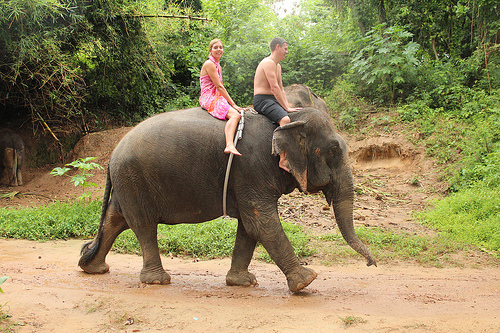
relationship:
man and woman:
[252, 32, 301, 92] [197, 37, 243, 158]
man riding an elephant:
[252, 32, 301, 92] [33, 60, 386, 328]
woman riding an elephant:
[197, 37, 243, 158] [33, 60, 386, 328]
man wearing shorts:
[252, 37, 293, 173] [256, 88, 283, 123]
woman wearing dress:
[197, 37, 243, 158] [194, 57, 234, 131]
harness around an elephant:
[222, 110, 247, 217] [85, 90, 374, 306]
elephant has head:
[77, 84, 378, 293] [266, 93, 377, 271]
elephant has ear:
[77, 84, 378, 293] [265, 115, 311, 196]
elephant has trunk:
[77, 104, 382, 297] [319, 162, 382, 274]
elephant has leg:
[77, 104, 382, 297] [234, 185, 319, 299]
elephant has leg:
[77, 104, 382, 297] [223, 211, 262, 290]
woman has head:
[197, 37, 243, 158] [205, 35, 227, 64]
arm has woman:
[201, 59, 245, 116] [197, 37, 243, 158]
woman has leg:
[197, 37, 243, 158] [201, 94, 244, 162]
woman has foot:
[197, 37, 243, 158] [215, 139, 242, 162]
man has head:
[252, 37, 293, 173] [265, 35, 295, 65]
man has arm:
[252, 37, 293, 173] [259, 59, 299, 116]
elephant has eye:
[77, 84, 378, 293] [328, 141, 342, 155]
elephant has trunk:
[77, 104, 382, 297] [317, 164, 383, 268]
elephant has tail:
[77, 84, 378, 293] [72, 157, 114, 267]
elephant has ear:
[77, 104, 382, 297] [264, 115, 321, 198]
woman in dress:
[190, 31, 243, 161] [195, 51, 233, 127]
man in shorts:
[252, 37, 293, 173] [252, 90, 300, 177]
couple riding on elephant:
[195, 35, 306, 180] [77, 104, 382, 297]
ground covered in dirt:
[3, 235, 496, 332] [0, 235, 499, 331]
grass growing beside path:
[405, 182, 499, 266] [1, 231, 499, 331]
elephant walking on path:
[77, 104, 382, 297] [0, 213, 499, 331]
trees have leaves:
[2, 0, 217, 200] [35, 14, 153, 111]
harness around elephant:
[211, 101, 248, 229] [77, 84, 378, 293]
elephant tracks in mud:
[397, 283, 467, 311] [2, 236, 499, 321]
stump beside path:
[1, 133, 32, 191] [1, 231, 499, 331]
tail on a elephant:
[78, 156, 114, 268] [77, 84, 378, 293]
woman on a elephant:
[197, 37, 243, 158] [77, 84, 378, 293]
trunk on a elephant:
[328, 180, 378, 269] [77, 84, 378, 293]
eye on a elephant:
[324, 147, 336, 157] [77, 84, 378, 293]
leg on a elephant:
[238, 205, 323, 294] [77, 84, 378, 293]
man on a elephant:
[252, 37, 293, 173] [77, 84, 378, 293]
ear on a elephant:
[271, 120, 309, 192] [77, 84, 378, 293]